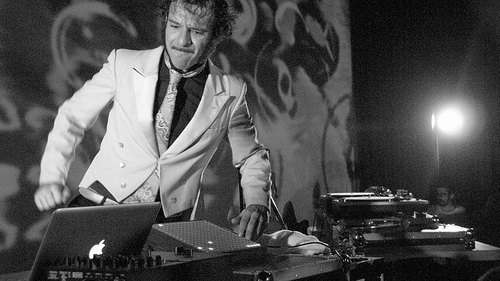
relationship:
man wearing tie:
[25, 0, 286, 255] [157, 42, 204, 156]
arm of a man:
[232, 83, 276, 239] [25, 0, 286, 255]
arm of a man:
[37, 48, 113, 210] [25, 0, 286, 255]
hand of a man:
[235, 205, 265, 238] [25, 0, 286, 255]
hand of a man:
[37, 183, 70, 211] [25, 0, 286, 255]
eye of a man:
[167, 19, 179, 33] [25, 0, 286, 255]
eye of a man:
[188, 29, 211, 38] [25, 0, 286, 255]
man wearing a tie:
[25, 0, 286, 255] [157, 42, 204, 156]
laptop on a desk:
[16, 198, 162, 280] [3, 233, 383, 279]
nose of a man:
[173, 29, 195, 49] [25, 0, 286, 255]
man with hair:
[25, 0, 286, 255] [153, 0, 243, 38]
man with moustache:
[25, 0, 286, 255] [169, 44, 196, 58]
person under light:
[430, 182, 467, 222] [434, 103, 467, 137]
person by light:
[430, 182, 467, 222] [434, 103, 467, 137]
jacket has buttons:
[39, 44, 275, 218] [110, 135, 135, 191]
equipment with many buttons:
[45, 240, 230, 278] [45, 255, 171, 267]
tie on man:
[157, 42, 204, 156] [25, 0, 286, 255]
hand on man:
[235, 205, 265, 238] [25, 0, 286, 255]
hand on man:
[37, 183, 70, 211] [25, 0, 286, 255]